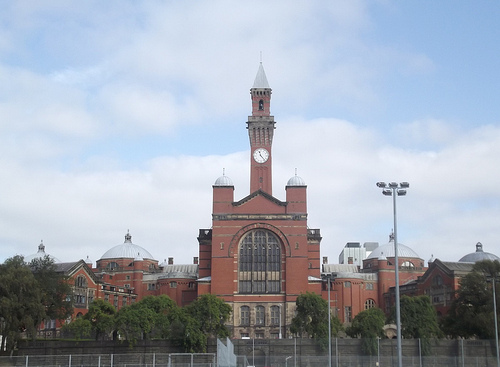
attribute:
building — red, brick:
[196, 50, 323, 339]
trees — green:
[0, 253, 499, 345]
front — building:
[1, 51, 499, 337]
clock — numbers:
[252, 147, 271, 165]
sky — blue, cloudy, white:
[1, 3, 497, 267]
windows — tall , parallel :
[240, 296, 281, 340]